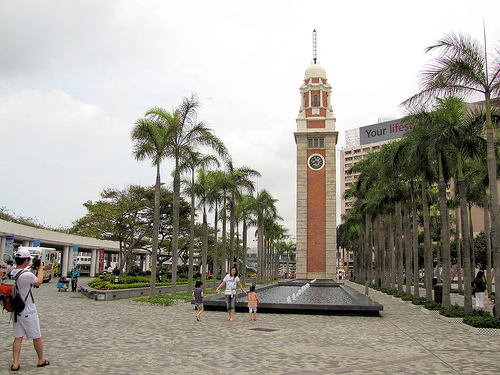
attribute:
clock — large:
[305, 149, 326, 173]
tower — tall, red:
[292, 26, 341, 280]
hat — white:
[15, 245, 36, 260]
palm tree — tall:
[132, 93, 182, 300]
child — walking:
[190, 276, 207, 324]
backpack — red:
[2, 268, 29, 316]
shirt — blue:
[69, 267, 79, 281]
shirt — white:
[222, 273, 240, 295]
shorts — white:
[247, 307, 260, 314]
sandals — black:
[8, 360, 53, 370]